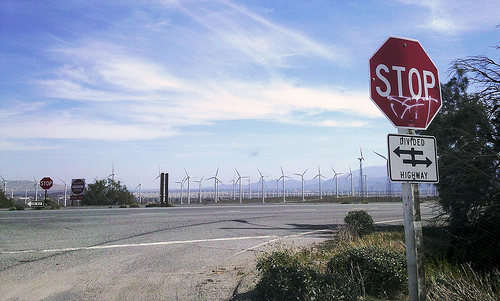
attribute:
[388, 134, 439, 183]
sign — here, white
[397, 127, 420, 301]
pole — metal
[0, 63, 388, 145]
cloud — white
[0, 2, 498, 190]
sky — clear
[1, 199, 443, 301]
street — here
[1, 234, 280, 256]
line — white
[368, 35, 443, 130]
sign — red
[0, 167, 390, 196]
mountain — here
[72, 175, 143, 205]
bush — green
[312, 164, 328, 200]
turbine — here